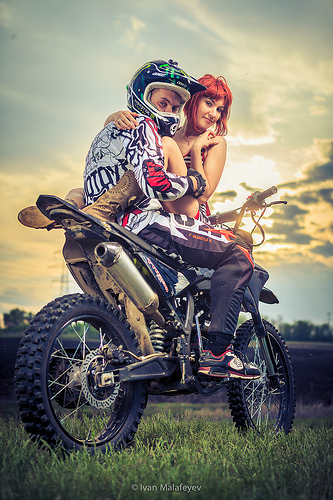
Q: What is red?
A: Hair.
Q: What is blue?
A: Sky.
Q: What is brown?
A: Boots.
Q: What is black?
A: Tires.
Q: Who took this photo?
A: Ivan Malafeyev.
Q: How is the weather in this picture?
A: Cloudy.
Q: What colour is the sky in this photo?
A: Blue and white.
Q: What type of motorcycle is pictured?
A: Dirt Bike.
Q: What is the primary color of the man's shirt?
A: White.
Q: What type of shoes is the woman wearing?
A: Boots.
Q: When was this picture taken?
A: Sunset.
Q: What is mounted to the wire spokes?
A: Black rim and knobby tire.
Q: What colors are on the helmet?
A: Black, white, neon yellow and green.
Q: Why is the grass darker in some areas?
A: Shadows from motorcycle.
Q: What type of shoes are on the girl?
A: Tan cowboy boots.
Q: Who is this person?
A: Red-headed girl.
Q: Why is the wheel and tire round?
A: So the motorcycle will roll easily.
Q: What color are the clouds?
A: White and grey.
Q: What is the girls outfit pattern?
A: Black and white striped with red trim.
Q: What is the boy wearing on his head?
A: A helmet.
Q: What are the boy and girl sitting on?
A: A motorbike.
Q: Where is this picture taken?
A: In a field.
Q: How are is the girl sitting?
A: With her legs around the boy.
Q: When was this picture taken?
A: Sunset.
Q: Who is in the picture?
A: A boy and girl.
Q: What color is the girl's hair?
A: Red.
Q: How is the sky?
A: Cloudy.